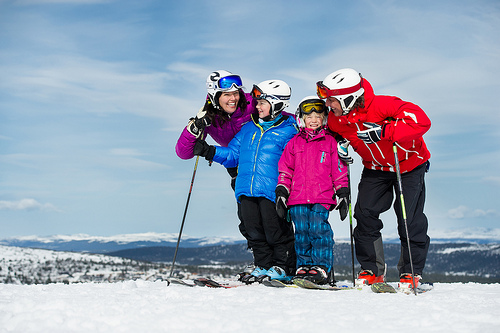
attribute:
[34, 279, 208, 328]
snow — covered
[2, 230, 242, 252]
mountain — snow-capped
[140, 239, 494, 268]
mountain — dark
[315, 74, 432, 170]
jacket — red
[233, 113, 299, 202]
winter jacket — blue, Bright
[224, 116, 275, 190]
jacket — blue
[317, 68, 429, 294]
women — skiing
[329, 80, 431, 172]
jacket — red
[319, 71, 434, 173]
ski gear — red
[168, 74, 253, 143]
mother — leaning 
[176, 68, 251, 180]
female — adult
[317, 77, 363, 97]
goggles — red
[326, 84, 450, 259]
father — leaning 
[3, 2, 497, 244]
sky — cloudy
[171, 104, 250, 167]
jacket — purple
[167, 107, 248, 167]
jacket — purple